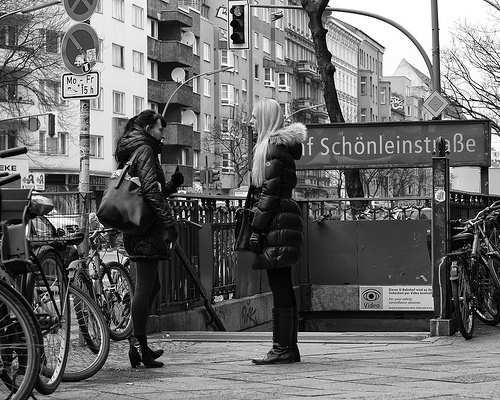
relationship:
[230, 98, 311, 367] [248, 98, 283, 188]
woman has hair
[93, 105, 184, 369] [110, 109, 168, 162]
woman with hair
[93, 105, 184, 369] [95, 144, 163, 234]
woman has purse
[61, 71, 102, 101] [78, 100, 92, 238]
sign on post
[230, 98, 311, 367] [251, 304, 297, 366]
woman wearing boot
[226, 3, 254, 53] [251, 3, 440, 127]
signal on pole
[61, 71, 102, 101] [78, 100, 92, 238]
sign on pole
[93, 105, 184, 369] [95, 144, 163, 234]
woman carrying purse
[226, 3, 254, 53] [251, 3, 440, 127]
traffic light attached to pole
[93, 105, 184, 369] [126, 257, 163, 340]
woman wearing leggings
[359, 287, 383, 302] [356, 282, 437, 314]
eye on sign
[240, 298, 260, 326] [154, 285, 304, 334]
graffitti on concrete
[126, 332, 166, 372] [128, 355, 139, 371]
boot has heel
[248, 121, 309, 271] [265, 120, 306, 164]
jacket has hood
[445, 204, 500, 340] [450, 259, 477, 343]
bike has wheel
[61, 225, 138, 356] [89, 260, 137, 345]
bike has wheel